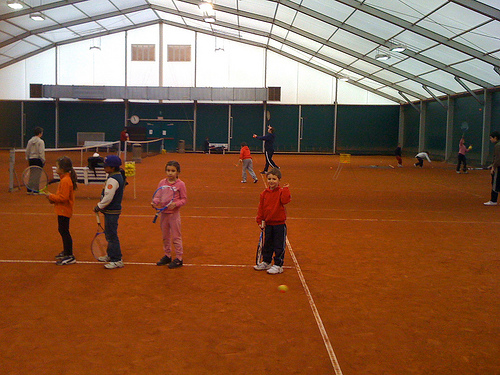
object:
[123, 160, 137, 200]
basket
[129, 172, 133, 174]
tennis balls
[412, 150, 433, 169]
child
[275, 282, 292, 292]
tennis ball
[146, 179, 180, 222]
tennis racket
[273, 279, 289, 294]
ball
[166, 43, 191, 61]
signs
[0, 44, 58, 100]
windows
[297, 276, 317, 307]
line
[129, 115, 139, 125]
clock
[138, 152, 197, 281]
girl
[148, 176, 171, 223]
raquet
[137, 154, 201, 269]
girl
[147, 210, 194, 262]
pants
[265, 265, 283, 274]
shoes on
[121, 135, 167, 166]
net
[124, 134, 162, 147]
trim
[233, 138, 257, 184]
kid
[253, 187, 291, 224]
coat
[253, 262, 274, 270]
shoes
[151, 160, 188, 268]
girl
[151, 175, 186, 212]
shirt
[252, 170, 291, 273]
boy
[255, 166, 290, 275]
boy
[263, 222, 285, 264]
pants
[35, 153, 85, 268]
girl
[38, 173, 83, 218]
sweatshirt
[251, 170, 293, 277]
child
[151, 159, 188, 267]
child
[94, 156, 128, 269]
child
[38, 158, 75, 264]
child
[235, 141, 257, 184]
child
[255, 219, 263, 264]
tennis racket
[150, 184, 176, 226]
tennis racket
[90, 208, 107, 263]
tennis racket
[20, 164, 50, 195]
tennis racket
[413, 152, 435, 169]
person bending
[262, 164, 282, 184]
hair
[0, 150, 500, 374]
tennis court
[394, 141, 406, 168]
child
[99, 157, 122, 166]
cap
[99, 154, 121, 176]
head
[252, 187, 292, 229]
sweater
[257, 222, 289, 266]
sweatpants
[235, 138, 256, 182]
children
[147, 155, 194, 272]
girl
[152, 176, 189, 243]
pink shirt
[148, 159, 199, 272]
girl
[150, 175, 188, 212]
sweater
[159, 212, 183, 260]
pants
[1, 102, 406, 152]
wall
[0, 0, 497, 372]
building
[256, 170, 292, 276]
kid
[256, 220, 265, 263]
racket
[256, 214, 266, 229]
hand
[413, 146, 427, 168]
kid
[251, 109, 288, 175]
man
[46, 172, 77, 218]
orange sweater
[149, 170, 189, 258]
outfit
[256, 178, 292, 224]
shirt